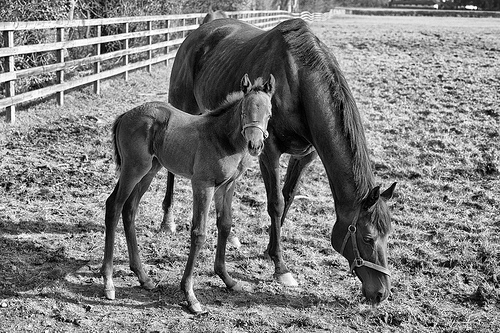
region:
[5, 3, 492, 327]
mother and foal in a fenced in area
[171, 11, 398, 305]
mare eating in a fenced in area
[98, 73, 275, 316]
foal in a fenced in area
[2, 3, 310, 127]
wooden fencing of a horse pen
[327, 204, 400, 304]
head of a horse with a halter on it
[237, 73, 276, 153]
head of a foal with a halter on it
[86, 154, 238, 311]
legs of a foal in a fenced in area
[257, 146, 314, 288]
front legs of a mare in a fenced in area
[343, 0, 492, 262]
sparse grass in a fenced in area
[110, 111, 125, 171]
tail of a foal standing with his mother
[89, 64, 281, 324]
this is a horse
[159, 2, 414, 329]
this is a horse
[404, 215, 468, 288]
this is grass on the field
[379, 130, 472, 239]
this is grass on the field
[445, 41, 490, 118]
this is grass on the field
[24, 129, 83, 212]
this is grass on the field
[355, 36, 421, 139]
this is grass on the field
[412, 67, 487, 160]
this is grass on the field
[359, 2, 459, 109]
this is grass on the field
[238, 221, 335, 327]
this is grass on the field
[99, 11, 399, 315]
Two horses with their ribs showing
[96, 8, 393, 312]
Colt standing next to its mother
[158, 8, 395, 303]
Horse eating the grass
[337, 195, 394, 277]
Horse's briddle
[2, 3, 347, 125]
Wooden fence next to a field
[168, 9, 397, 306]
Dark horse in a field of grass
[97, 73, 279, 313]
Light colored colt with very long legs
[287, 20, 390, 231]
Dark colored mane on a horse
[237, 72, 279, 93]
Pair of horse ears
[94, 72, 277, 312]
Colt standing in a field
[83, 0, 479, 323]
two horses in a pasture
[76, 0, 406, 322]
a mare and its foal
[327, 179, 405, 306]
the head of a horse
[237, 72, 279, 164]
the head of a pony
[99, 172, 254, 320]
the legs of a pony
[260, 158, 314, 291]
the front legs of a horse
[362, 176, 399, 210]
the ears of a horse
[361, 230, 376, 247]
the eye of a horse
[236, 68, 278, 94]
the ears of a pony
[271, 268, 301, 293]
the hoof of a horse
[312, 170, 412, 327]
the horse is eating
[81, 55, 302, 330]
the horse is skinny